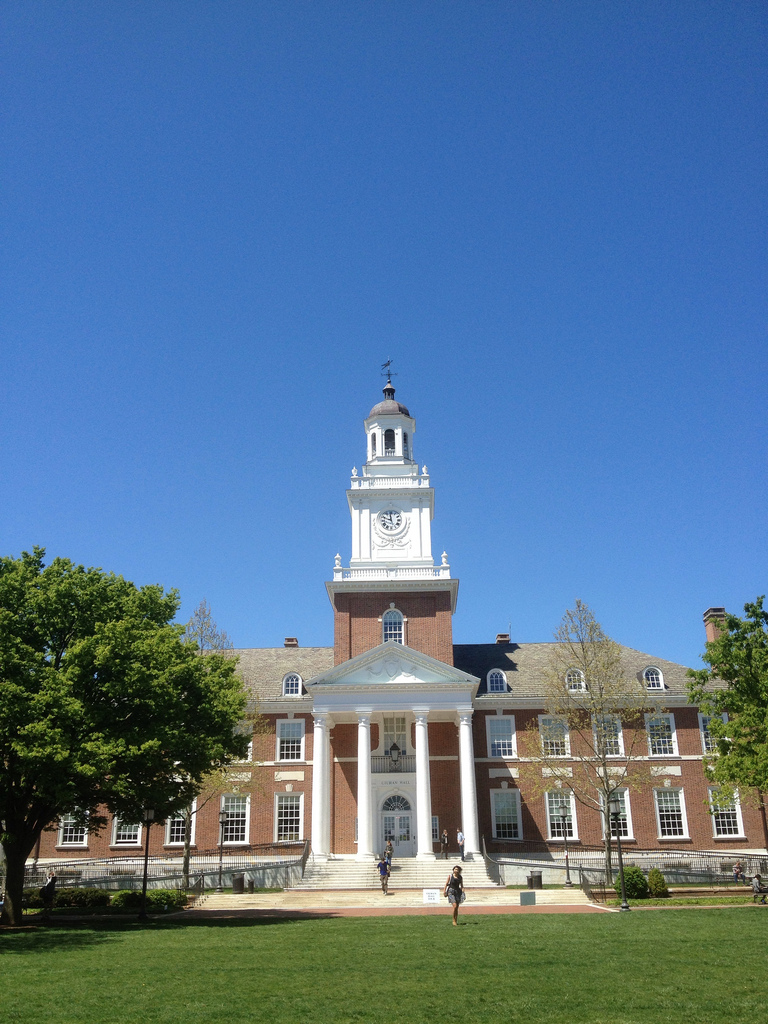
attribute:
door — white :
[361, 777, 419, 871]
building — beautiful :
[21, 350, 756, 900]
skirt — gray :
[446, 884, 463, 903]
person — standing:
[455, 828, 465, 859]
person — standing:
[439, 826, 449, 858]